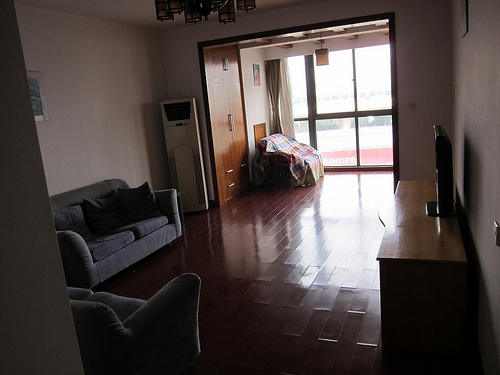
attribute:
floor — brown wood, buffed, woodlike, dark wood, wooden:
[115, 159, 400, 370]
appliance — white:
[156, 89, 231, 224]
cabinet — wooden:
[373, 165, 485, 362]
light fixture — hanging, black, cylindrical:
[149, 4, 259, 36]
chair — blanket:
[251, 126, 327, 197]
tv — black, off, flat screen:
[427, 121, 465, 234]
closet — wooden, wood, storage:
[201, 47, 262, 199]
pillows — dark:
[79, 175, 161, 234]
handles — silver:
[227, 115, 236, 137]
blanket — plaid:
[275, 140, 332, 188]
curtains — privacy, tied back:
[262, 57, 288, 140]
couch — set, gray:
[43, 174, 185, 279]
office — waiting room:
[10, 6, 483, 366]